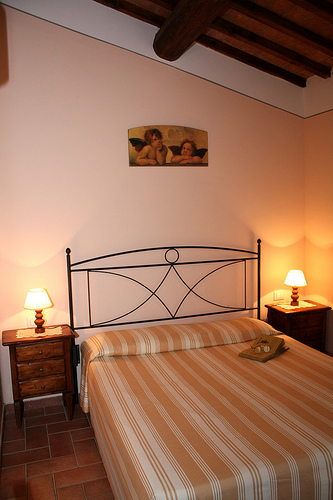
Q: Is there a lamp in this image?
A: Yes, there is a lamp.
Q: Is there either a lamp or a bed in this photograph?
A: Yes, there is a lamp.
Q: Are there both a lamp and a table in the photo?
A: Yes, there are both a lamp and a table.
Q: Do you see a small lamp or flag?
A: Yes, there is a small lamp.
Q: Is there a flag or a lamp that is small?
A: Yes, the lamp is small.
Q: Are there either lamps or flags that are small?
A: Yes, the lamp is small.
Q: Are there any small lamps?
A: Yes, there is a small lamp.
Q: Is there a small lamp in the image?
A: Yes, there is a small lamp.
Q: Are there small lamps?
A: Yes, there is a small lamp.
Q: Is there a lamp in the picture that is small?
A: Yes, there is a lamp that is small.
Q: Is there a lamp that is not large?
A: Yes, there is a small lamp.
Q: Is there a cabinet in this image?
A: No, there are no cabinets.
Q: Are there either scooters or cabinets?
A: No, there are no cabinets or scooters.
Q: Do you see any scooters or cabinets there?
A: No, there are no cabinets or scooters.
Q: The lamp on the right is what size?
A: The lamp is small.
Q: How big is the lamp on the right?
A: The lamp is small.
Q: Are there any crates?
A: No, there are no crates.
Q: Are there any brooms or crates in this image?
A: No, there are no crates or brooms.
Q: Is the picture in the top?
A: Yes, the picture is in the top of the image.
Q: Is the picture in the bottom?
A: No, the picture is in the top of the image.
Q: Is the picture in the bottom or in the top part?
A: The picture is in the top of the image.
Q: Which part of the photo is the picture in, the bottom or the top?
A: The picture is in the top of the image.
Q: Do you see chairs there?
A: No, there are no chairs.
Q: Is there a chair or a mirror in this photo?
A: No, there are no chairs or mirrors.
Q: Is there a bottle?
A: No, there are no bottles.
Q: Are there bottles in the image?
A: No, there are no bottles.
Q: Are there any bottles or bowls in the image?
A: No, there are no bottles or bowls.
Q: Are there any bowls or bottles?
A: No, there are no bottles or bowls.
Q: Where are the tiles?
A: The tiles are on the floor.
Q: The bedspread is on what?
A: The bedspread is on the bed.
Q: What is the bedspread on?
A: The bedspread is on the bed.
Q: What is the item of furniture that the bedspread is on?
A: The piece of furniture is a bed.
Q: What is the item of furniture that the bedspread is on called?
A: The piece of furniture is a bed.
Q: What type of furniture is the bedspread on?
A: The bedspread is on the bed.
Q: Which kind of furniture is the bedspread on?
A: The bedspread is on the bed.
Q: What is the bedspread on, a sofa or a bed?
A: The bedspread is on a bed.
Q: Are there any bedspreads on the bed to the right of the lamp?
A: Yes, there is a bedspread on the bed.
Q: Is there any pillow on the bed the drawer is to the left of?
A: No, there is a bedspread on the bed.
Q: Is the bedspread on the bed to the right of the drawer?
A: Yes, the bedspread is on the bed.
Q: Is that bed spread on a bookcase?
A: No, the bed spread is on the bed.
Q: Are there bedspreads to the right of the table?
A: Yes, there is a bedspread to the right of the table.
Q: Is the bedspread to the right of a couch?
A: No, the bedspread is to the right of the table.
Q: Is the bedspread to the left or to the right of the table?
A: The bedspread is to the right of the table.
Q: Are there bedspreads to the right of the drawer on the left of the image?
A: Yes, there is a bedspread to the right of the drawer.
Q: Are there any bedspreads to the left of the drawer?
A: No, the bedspread is to the right of the drawer.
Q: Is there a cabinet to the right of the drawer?
A: No, there is a bedspread to the right of the drawer.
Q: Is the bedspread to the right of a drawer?
A: Yes, the bedspread is to the right of a drawer.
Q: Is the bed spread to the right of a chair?
A: No, the bed spread is to the right of a drawer.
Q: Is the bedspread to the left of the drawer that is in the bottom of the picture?
A: No, the bedspread is to the right of the drawer.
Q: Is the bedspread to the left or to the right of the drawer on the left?
A: The bedspread is to the right of the drawer.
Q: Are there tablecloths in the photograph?
A: No, there are no tablecloths.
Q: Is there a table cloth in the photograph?
A: No, there are no tablecloths.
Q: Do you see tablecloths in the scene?
A: No, there are no tablecloths.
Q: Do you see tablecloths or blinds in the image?
A: No, there are no tablecloths or blinds.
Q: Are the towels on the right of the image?
A: Yes, the towels are on the right of the image.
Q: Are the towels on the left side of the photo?
A: No, the towels are on the right of the image.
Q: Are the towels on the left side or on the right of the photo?
A: The towels are on the right of the image.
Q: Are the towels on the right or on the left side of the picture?
A: The towels are on the right of the image.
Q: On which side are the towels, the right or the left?
A: The towels are on the right of the image.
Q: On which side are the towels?
A: The towels are on the right of the image.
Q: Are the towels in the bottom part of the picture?
A: Yes, the towels are in the bottom of the image.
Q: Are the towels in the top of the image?
A: No, the towels are in the bottom of the image.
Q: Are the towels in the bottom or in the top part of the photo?
A: The towels are in the bottom of the image.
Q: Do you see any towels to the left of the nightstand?
A: Yes, there are towels to the left of the nightstand.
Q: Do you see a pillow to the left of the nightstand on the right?
A: No, there are towels to the left of the nightstand.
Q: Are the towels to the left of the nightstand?
A: Yes, the towels are to the left of the nightstand.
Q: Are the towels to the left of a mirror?
A: No, the towels are to the left of the nightstand.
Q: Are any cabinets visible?
A: No, there are no cabinets.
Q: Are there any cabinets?
A: No, there are no cabinets.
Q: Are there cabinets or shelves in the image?
A: No, there are no cabinets or shelves.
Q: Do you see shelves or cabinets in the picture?
A: No, there are no cabinets or shelves.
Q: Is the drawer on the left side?
A: Yes, the drawer is on the left of the image.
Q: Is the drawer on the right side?
A: No, the drawer is on the left of the image.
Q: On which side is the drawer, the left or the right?
A: The drawer is on the left of the image.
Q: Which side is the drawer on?
A: The drawer is on the left of the image.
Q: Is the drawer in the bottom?
A: Yes, the drawer is in the bottom of the image.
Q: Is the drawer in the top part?
A: No, the drawer is in the bottom of the image.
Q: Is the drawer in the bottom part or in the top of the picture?
A: The drawer is in the bottom of the image.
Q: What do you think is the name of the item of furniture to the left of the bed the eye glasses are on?
A: The piece of furniture is a drawer.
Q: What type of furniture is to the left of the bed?
A: The piece of furniture is a drawer.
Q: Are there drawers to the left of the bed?
A: Yes, there is a drawer to the left of the bed.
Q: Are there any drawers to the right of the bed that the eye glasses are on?
A: No, the drawer is to the left of the bed.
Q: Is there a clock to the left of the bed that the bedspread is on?
A: No, there is a drawer to the left of the bed.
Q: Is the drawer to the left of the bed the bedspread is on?
A: Yes, the drawer is to the left of the bed.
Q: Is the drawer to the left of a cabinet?
A: No, the drawer is to the left of the bed.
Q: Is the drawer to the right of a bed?
A: No, the drawer is to the left of a bed.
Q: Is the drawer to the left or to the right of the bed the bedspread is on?
A: The drawer is to the left of the bed.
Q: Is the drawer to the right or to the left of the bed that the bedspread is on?
A: The drawer is to the left of the bed.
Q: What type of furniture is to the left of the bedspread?
A: The piece of furniture is a drawer.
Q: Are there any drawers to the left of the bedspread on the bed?
A: Yes, there is a drawer to the left of the bedspread.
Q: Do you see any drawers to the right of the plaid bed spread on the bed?
A: No, the drawer is to the left of the bedspread.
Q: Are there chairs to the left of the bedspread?
A: No, there is a drawer to the left of the bedspread.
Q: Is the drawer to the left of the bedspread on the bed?
A: Yes, the drawer is to the left of the bedspread.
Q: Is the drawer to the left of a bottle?
A: No, the drawer is to the left of the bedspread.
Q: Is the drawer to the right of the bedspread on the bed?
A: No, the drawer is to the left of the bedspread.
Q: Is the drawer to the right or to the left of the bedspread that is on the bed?
A: The drawer is to the left of the bedspread.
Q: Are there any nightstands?
A: Yes, there is a nightstand.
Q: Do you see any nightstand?
A: Yes, there is a nightstand.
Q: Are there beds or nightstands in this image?
A: Yes, there is a nightstand.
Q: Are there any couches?
A: No, there are no couches.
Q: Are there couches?
A: No, there are no couches.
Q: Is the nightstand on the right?
A: Yes, the nightstand is on the right of the image.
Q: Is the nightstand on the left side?
A: No, the nightstand is on the right of the image.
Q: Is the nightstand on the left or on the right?
A: The nightstand is on the right of the image.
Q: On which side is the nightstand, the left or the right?
A: The nightstand is on the right of the image.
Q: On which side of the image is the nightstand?
A: The nightstand is on the right of the image.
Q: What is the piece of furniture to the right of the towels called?
A: The piece of furniture is a nightstand.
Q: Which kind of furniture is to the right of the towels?
A: The piece of furniture is a nightstand.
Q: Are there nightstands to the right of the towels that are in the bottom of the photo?
A: Yes, there is a nightstand to the right of the towels.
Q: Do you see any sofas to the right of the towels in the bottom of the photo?
A: No, there is a nightstand to the right of the towels.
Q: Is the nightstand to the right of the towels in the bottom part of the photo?
A: Yes, the nightstand is to the right of the towels.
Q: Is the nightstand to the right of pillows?
A: No, the nightstand is to the right of the towels.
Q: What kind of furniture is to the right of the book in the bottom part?
A: The piece of furniture is a nightstand.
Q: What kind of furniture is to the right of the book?
A: The piece of furniture is a nightstand.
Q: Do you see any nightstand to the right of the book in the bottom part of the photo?
A: Yes, there is a nightstand to the right of the book.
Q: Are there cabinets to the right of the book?
A: No, there is a nightstand to the right of the book.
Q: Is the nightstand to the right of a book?
A: Yes, the nightstand is to the right of a book.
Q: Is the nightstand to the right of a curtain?
A: No, the nightstand is to the right of a book.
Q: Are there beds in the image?
A: Yes, there is a bed.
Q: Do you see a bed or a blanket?
A: Yes, there is a bed.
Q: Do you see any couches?
A: No, there are no couches.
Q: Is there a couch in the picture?
A: No, there are no couches.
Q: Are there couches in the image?
A: No, there are no couches.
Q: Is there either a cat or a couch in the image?
A: No, there are no couches or cats.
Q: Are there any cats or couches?
A: No, there are no couches or cats.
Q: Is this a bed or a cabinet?
A: This is a bed.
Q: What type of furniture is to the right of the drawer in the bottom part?
A: The piece of furniture is a bed.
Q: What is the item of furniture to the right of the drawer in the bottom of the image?
A: The piece of furniture is a bed.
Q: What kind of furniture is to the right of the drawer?
A: The piece of furniture is a bed.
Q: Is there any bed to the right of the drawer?
A: Yes, there is a bed to the right of the drawer.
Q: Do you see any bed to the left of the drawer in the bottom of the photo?
A: No, the bed is to the right of the drawer.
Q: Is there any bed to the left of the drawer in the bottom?
A: No, the bed is to the right of the drawer.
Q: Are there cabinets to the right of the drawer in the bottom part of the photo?
A: No, there is a bed to the right of the drawer.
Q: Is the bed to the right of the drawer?
A: Yes, the bed is to the right of the drawer.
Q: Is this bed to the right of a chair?
A: No, the bed is to the right of the drawer.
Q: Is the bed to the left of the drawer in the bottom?
A: No, the bed is to the right of the drawer.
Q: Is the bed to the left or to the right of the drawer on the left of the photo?
A: The bed is to the right of the drawer.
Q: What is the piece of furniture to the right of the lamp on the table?
A: The piece of furniture is a bed.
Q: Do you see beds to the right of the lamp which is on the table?
A: Yes, there is a bed to the right of the lamp.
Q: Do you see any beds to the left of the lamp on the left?
A: No, the bed is to the right of the lamp.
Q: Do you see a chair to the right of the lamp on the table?
A: No, there is a bed to the right of the lamp.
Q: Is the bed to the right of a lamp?
A: Yes, the bed is to the right of a lamp.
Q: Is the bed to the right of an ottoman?
A: No, the bed is to the right of a lamp.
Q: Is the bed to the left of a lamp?
A: No, the bed is to the right of a lamp.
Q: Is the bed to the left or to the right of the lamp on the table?
A: The bed is to the right of the lamp.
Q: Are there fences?
A: No, there are no fences.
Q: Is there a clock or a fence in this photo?
A: No, there are no fences or clocks.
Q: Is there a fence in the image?
A: No, there are no fences.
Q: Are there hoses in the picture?
A: No, there are no hoses.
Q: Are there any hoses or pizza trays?
A: No, there are no hoses or pizza trays.